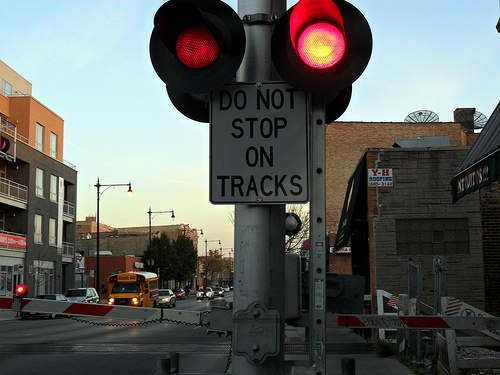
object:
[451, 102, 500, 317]
building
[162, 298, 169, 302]
lights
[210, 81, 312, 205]
sign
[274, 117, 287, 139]
letter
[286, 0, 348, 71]
light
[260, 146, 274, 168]
black letter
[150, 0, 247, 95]
light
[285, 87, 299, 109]
letter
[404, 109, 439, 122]
satellite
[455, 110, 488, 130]
satellite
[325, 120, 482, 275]
building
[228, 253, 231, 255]
street lamp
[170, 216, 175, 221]
street lamp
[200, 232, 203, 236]
street lamp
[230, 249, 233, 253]
street lamp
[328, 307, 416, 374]
roadside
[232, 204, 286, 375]
gray pole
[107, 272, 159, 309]
bus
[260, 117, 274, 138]
letter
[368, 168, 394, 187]
sign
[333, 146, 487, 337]
building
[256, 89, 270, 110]
letter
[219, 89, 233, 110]
letter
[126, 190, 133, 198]
light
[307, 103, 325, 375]
pole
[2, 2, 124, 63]
sky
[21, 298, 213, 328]
rail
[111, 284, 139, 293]
windshield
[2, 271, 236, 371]
street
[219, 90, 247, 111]
do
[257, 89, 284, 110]
not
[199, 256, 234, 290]
buildings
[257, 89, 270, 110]
black letter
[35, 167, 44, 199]
window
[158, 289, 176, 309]
car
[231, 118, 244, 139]
s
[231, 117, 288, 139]
stop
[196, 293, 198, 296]
lights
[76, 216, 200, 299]
building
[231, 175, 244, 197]
black letter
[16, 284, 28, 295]
light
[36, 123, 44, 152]
window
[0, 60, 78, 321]
building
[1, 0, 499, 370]
rail crossing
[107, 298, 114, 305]
light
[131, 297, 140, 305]
light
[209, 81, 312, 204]
sign board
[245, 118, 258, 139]
letters